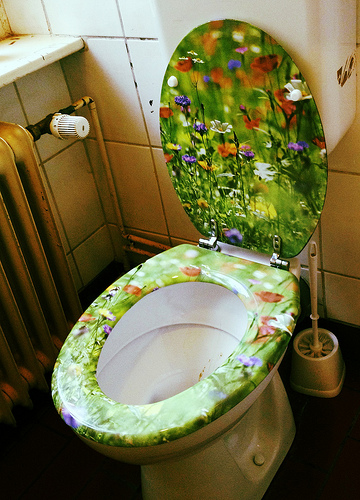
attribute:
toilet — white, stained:
[78, 89, 314, 499]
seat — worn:
[55, 231, 304, 434]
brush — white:
[298, 239, 337, 338]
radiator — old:
[10, 97, 76, 422]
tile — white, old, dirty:
[93, 25, 177, 234]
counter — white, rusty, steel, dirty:
[1, 14, 81, 72]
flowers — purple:
[173, 56, 293, 234]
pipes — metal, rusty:
[73, 97, 167, 263]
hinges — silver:
[190, 241, 289, 273]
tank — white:
[161, 7, 359, 155]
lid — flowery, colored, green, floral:
[165, 28, 325, 261]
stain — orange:
[168, 313, 262, 415]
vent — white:
[52, 111, 95, 151]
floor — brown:
[295, 400, 357, 499]